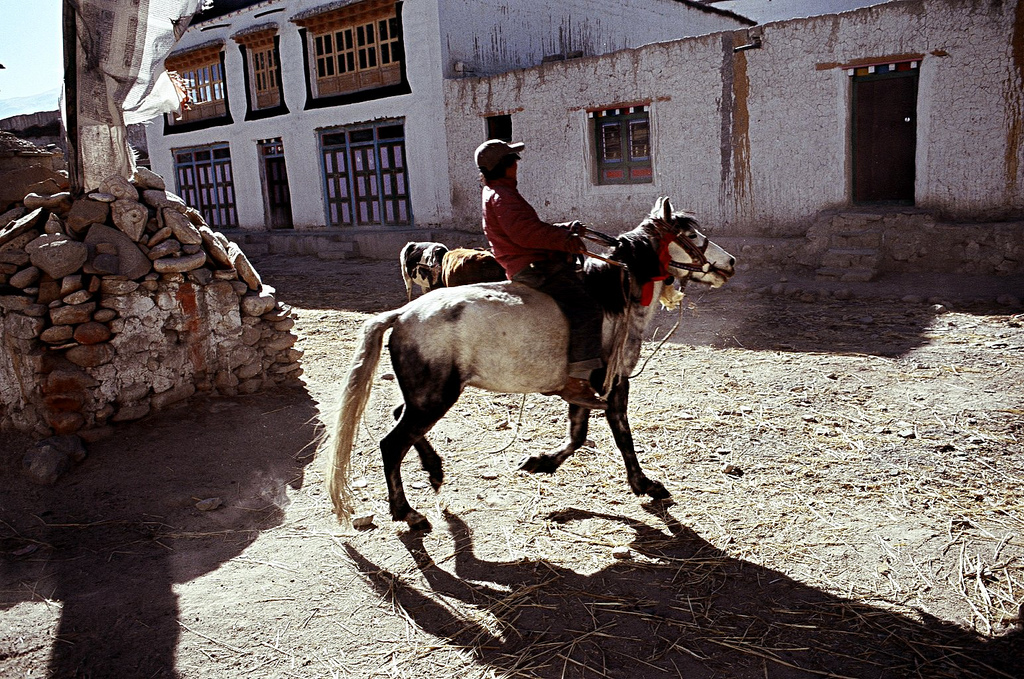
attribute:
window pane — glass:
[367, 23, 396, 60]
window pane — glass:
[344, 23, 377, 52]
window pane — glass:
[326, 45, 366, 74]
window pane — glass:
[311, 26, 333, 81]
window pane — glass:
[367, 138, 393, 167]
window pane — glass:
[370, 187, 396, 227]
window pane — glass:
[240, 45, 290, 110]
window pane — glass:
[241, 26, 281, 109]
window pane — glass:
[165, 39, 224, 117]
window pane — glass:
[158, 43, 236, 134]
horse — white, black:
[329, 197, 738, 528]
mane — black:
[603, 203, 699, 273]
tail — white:
[323, 313, 397, 523]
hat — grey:
[465, 134, 522, 171]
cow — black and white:
[430, 246, 487, 262]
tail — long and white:
[343, 393, 369, 426]